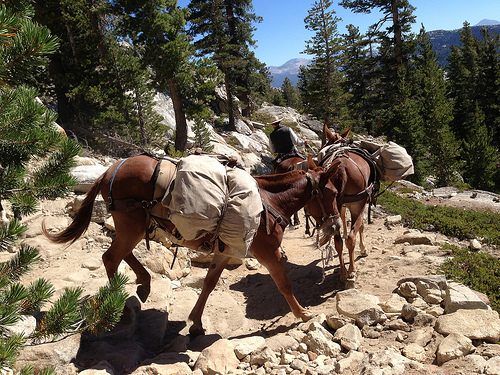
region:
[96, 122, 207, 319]
the horse is brown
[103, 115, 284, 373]
the horse is brown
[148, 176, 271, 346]
the horse is brown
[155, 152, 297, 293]
the horse is brown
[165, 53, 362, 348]
the horse is brown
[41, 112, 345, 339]
dark brown horse with long straight tail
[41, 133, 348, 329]
dark brown horse with chestnut colored mane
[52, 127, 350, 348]
horse carrying saddlebags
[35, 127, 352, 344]
horse carrying bags of supplies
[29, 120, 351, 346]
horse traveling over rocky terrain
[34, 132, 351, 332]
horse traveling on mountain path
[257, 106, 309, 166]
man wearing black vest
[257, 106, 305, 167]
man wearing white long sleeved shirt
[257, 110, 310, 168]
man wearing cowboy hat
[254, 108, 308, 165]
man leading horses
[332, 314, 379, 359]
large rocks on the ground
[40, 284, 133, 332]
pine needles on tree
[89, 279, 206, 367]
the horse's shadow on the ground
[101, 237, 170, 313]
horse's foot off the ground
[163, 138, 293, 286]
sack on the horse's back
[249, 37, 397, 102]
beautiful blue mountain range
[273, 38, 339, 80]
sunshine on the mountain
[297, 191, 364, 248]
reins around horse's face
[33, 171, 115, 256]
beautiful bushy brown tail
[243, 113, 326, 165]
rider on the horse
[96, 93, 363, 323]
a horse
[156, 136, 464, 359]
a horse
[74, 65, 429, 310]
horses on the trail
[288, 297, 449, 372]
rocks on the trail side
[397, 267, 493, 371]
rocks in a pile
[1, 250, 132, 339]
pine needles on the tree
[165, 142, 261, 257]
a bag slung on its back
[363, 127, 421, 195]
a bag on the horse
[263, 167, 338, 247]
the harness for the horse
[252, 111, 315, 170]
the amn rides the horse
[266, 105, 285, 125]
the tan cowboy hat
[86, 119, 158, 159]
the dead tree on the ground